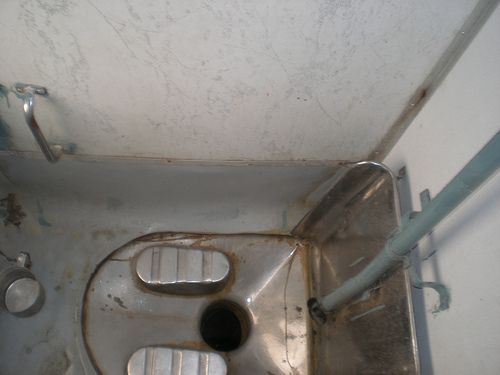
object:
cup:
[1, 246, 51, 317]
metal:
[12, 82, 76, 162]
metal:
[363, 0, 498, 162]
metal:
[1, 150, 420, 373]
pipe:
[322, 150, 499, 307]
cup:
[5, 266, 55, 327]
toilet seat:
[74, 222, 321, 374]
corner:
[361, 0, 498, 161]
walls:
[384, 0, 498, 372]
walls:
[0, 0, 478, 162]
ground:
[406, 136, 432, 181]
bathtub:
[2, 151, 422, 373]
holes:
[188, 289, 266, 364]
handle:
[5, 77, 87, 167]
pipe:
[320, 127, 499, 314]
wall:
[380, 3, 497, 373]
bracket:
[382, 186, 449, 313]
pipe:
[321, 181, 451, 313]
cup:
[6, 245, 66, 311]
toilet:
[75, 185, 390, 359]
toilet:
[48, 157, 435, 373]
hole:
[188, 291, 261, 353]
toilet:
[115, 222, 281, 364]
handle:
[16, 252, 31, 269]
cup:
[1, 251, 43, 316]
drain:
[193, 293, 253, 356]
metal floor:
[0, 200, 319, 373]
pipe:
[308, 137, 498, 307]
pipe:
[327, 185, 497, 282]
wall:
[433, 220, 496, 373]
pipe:
[320, 147, 485, 322]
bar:
[8, 80, 78, 165]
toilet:
[82, 234, 311, 372]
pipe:
[314, 92, 499, 324]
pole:
[318, 125, 498, 314]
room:
[4, 1, 499, 373]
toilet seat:
[84, 204, 351, 372]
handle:
[15, 80, 80, 182]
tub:
[74, 155, 424, 373]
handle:
[12, 75, 84, 192]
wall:
[4, 0, 452, 109]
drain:
[199, 297, 255, 352]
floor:
[8, 165, 326, 374]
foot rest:
[131, 232, 236, 296]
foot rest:
[116, 334, 232, 374]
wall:
[69, 4, 409, 154]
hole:
[196, 290, 261, 355]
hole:
[199, 298, 250, 353]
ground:
[30, 157, 316, 372]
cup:
[4, 240, 45, 320]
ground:
[2, 230, 103, 374]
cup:
[6, 250, 80, 325]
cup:
[0, 250, 44, 320]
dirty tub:
[4, 150, 426, 373]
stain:
[191, 233, 218, 244]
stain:
[296, 245, 308, 287]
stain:
[168, 340, 210, 349]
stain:
[59, 268, 75, 281]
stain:
[219, 286, 229, 293]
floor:
[12, 207, 317, 374]